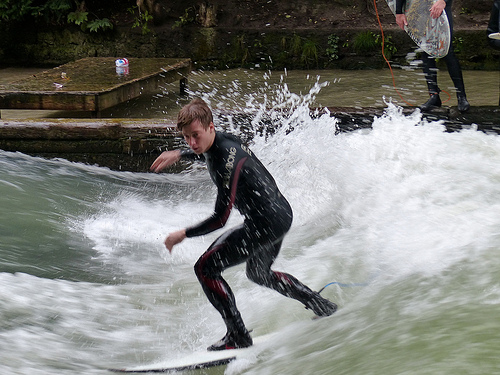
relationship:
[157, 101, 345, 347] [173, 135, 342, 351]
person wearing wetsuit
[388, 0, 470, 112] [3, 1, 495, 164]
person in background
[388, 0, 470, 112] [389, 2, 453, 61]
person holding surfboard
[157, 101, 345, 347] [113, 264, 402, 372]
person on surfboard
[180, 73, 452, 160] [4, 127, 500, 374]
splash of water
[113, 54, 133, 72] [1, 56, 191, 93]
bottle on bench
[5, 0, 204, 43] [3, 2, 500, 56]
plants growing on wall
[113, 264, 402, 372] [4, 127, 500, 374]
surfboard on water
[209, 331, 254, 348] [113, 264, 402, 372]
shoe on surfboard